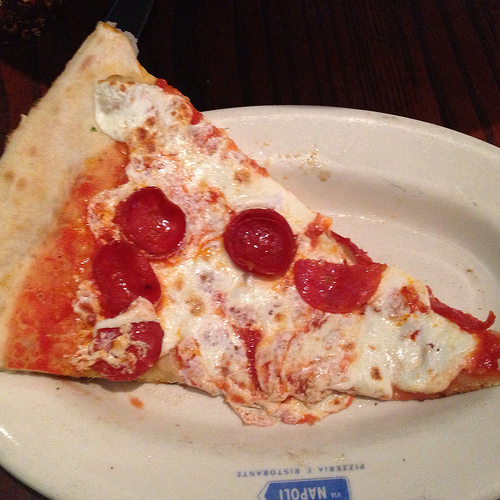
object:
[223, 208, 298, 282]
pepperoni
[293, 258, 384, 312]
pepperoni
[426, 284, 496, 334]
pepperoni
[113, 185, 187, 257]
pepperoni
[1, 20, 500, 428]
pizza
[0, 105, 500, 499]
plate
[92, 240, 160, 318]
pepperoni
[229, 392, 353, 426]
cheese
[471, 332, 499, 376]
sauce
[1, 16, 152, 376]
crust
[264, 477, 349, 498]
logo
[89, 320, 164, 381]
pepperoni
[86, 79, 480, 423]
cheese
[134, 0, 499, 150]
table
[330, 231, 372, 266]
pepperoni